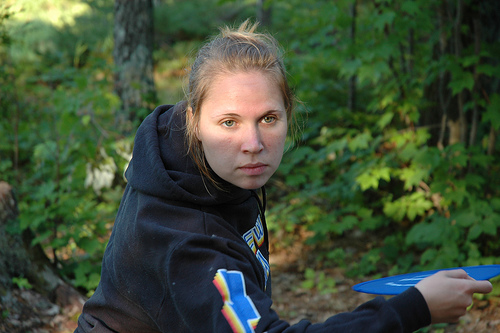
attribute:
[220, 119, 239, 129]
eye — blue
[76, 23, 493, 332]
woman — serious, gazing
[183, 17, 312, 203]
hair — blondish, brown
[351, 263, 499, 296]
frisbee — blue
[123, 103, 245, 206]
hood — black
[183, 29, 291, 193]
head — lined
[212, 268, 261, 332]
logo — blue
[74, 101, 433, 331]
shirt — blue, gray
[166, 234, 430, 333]
sleeve — blue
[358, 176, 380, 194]
leaf — behind, behidn